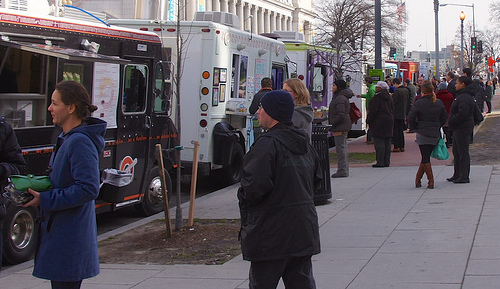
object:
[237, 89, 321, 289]
man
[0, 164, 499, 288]
sidewalk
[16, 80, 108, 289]
woman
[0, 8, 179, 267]
truck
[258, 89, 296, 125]
cap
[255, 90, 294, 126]
head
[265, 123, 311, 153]
hoodie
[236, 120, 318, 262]
jacket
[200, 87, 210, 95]
light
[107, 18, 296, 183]
food truck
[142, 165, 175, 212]
wheel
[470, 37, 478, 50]
traffic signal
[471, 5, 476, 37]
pole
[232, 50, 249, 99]
window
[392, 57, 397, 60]
light